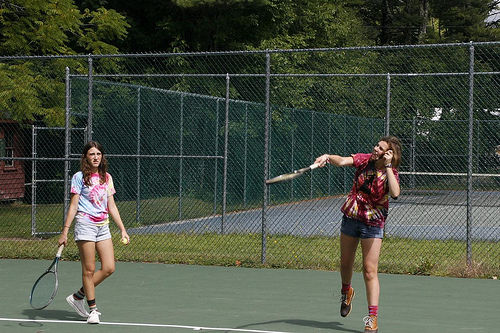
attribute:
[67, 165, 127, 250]
shirt — is blue, is white, is pink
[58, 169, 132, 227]
shirt — pink, blue, tie-dyed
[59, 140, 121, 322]
woman — wearing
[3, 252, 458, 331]
court — green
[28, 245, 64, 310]
tennis racket — is white, is blue, is gray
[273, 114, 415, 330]
lady — happy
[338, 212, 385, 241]
blue shorts — is blue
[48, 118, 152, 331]
lady — wearing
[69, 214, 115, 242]
shorts — light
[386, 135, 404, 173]
hair — curly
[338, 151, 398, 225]
shirt — tie-dyed, maroon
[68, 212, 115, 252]
shorts — white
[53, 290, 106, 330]
shoes — white and black